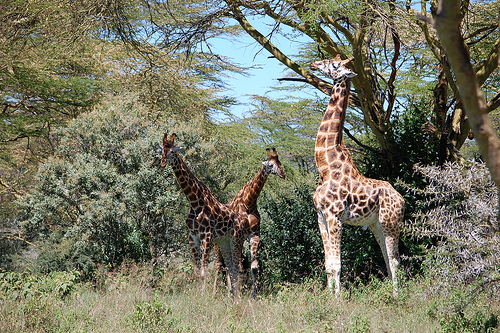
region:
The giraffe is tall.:
[293, 50, 413, 307]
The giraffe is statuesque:
[301, 43, 411, 308]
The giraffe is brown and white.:
[300, 49, 410, 306]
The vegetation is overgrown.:
[1, 273, 498, 331]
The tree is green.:
[28, 107, 202, 270]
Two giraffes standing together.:
[158, 125, 289, 305]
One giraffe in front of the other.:
[154, 129, 292, 306]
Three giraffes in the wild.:
[151, 49, 417, 313]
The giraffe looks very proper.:
[307, 51, 415, 308]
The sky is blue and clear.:
[109, 10, 312, 123]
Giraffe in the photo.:
[156, 135, 231, 281]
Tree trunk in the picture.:
[443, 42, 489, 132]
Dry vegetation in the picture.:
[222, 307, 314, 328]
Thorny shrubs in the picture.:
[432, 171, 482, 243]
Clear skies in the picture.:
[242, 58, 279, 89]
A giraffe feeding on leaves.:
[306, 49, 418, 295]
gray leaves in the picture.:
[77, 130, 134, 211]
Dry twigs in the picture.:
[158, 20, 211, 57]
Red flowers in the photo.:
[110, 257, 142, 282]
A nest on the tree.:
[7, 4, 39, 37]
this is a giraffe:
[307, 47, 415, 307]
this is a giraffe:
[224, 145, 289, 300]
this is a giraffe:
[153, 127, 245, 311]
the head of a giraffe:
[308, 35, 360, 101]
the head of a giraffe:
[258, 148, 293, 181]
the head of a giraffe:
[141, 125, 186, 175]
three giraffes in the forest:
[141, 33, 419, 316]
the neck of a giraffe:
[238, 164, 271, 209]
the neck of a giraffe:
[170, 150, 210, 204]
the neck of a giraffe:
[295, 78, 362, 160]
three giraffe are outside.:
[147, 48, 410, 294]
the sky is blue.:
[90, 0, 333, 135]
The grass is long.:
[0, 242, 497, 326]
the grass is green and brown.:
[2, 265, 499, 331]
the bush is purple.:
[390, 153, 499, 288]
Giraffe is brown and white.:
[299, 47, 409, 297]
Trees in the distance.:
[0, 3, 319, 275]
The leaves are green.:
[1, 3, 498, 268]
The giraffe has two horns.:
[156, 127, 181, 143]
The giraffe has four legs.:
[304, 165, 411, 302]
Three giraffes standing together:
[157, 52, 414, 303]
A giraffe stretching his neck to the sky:
[307, 52, 369, 175]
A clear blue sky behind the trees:
[177, 0, 302, 103]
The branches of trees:
[357, 0, 497, 159]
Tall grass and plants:
[0, 278, 297, 331]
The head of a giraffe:
[307, 52, 359, 87]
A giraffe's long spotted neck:
[310, 77, 360, 171]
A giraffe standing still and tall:
[308, 50, 412, 301]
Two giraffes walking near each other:
[157, 128, 287, 298]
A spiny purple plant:
[404, 159, 498, 296]